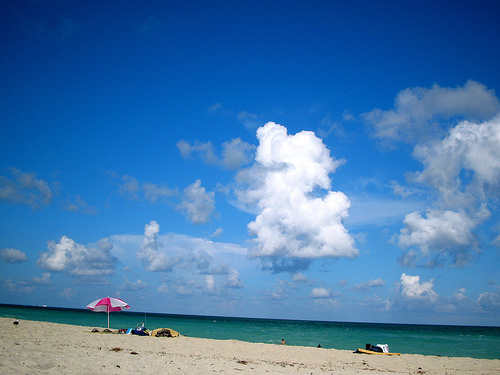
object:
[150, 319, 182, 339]
belongings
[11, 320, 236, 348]
sand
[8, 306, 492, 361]
ocean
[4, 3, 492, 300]
sky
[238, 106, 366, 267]
clouds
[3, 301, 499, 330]
line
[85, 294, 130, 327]
beach umbrella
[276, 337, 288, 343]
person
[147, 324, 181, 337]
blanket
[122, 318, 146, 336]
person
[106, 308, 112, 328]
stick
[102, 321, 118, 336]
belongings